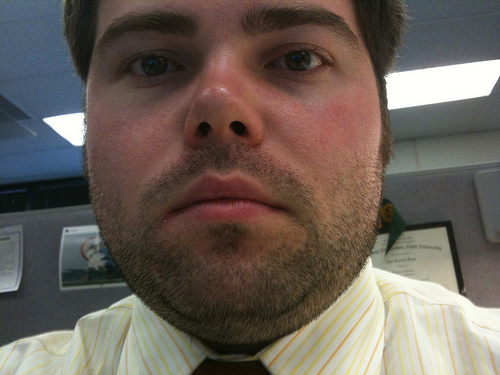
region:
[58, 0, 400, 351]
The man has hair.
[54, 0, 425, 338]
The man has eybrows.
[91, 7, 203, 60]
The eyebrow is arched.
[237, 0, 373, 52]
The eyebrow is arched.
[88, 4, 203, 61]
The eyebrow is brown.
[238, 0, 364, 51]
The eyebrow is brown.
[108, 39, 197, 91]
The eye is open.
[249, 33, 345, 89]
The eye is open.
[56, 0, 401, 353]
The man has a nose.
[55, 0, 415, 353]
The man has pink lips.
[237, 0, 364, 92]
A left human eye.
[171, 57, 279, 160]
a shiny human nose.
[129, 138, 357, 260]
a set of red lips.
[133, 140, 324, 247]
a mustache on a man.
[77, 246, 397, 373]
lapels on a shirt.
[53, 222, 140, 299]
a picture on a wall.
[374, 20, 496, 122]
a light in a ceiling.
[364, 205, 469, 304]
a framed certificate.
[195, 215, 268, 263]
a small dap of hair.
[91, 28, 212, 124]
a right human eye.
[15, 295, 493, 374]
The man is wearing a white shirt.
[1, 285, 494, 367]
The shirt is stripped yellow.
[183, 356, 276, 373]
His tie is brown.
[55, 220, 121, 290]
The picture is in the back.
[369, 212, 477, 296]
The degree is on the wall.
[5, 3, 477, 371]
He is in a cubicle.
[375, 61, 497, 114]
The light is on.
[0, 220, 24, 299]
The paper is on the wall.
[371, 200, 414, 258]
A green pennant is above the degree.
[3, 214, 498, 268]
The wall is grey.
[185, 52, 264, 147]
Nose on a man's face.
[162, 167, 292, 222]
Light red lips on a man's face.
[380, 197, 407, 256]
Green and yellow flag to the right of a man's head.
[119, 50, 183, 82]
A man's right side eye.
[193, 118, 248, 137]
Two dark nostrils on a man's nose.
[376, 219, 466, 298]
Black frame around a picture on the right of the mans head.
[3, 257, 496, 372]
White and yellow striped shirt on a man.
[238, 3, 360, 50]
A man's left side brown eyebrow.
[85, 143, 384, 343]
All of the man's facial hair growing below the nose.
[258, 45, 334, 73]
A man's left side eye.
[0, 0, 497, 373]
man taking a selfie picture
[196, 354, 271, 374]
part of mans tie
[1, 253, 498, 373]
mans yellow and orange striped shirt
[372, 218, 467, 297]
diploma behind the man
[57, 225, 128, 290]
art on the wall behind the man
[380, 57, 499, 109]
recessed lighting in the ceiling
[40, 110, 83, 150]
recessed lighting in the ceiling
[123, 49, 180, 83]
mans right eye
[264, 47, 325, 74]
mans left eye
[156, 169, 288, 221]
mans mouth